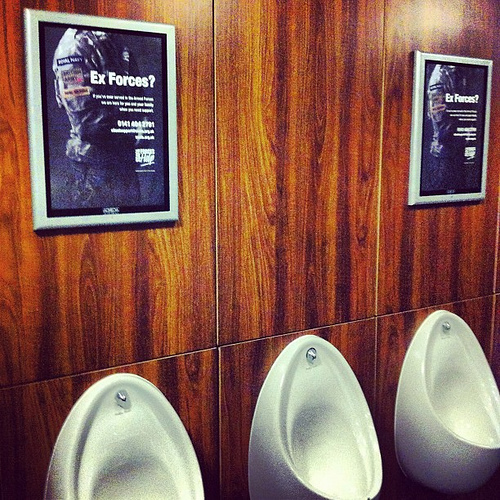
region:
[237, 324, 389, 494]
Urinal in a restroom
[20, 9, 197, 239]
Picture hanging on a bathroom wall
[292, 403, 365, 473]
Bowl portion on a urinal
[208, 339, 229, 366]
Seam between panels on a wall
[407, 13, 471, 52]
Light reflecting off a wall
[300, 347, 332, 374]
Metal portion of a urinal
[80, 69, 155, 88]
Letters on a picture on a wall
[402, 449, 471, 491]
Underside of a urinal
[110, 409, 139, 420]
Manufacturer name on a urinal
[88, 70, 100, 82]
white letter on poster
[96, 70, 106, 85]
white letter on poster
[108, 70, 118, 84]
white letter on poster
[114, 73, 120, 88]
white letter on poster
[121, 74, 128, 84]
white letter on poster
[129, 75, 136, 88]
white letter on poster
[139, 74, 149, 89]
white letter on poster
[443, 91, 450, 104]
white letter on poster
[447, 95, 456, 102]
white letter on poster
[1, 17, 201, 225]
grey frame around poster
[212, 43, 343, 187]
brown wall near poster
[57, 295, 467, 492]
white urinals on wall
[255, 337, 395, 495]
urinals are white and round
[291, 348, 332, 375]
metal button on urinal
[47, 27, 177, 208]
white ad on picture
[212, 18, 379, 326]
brown and wooden panels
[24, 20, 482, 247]
two posters on wall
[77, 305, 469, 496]
urinals near each other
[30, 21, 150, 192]
person in poster picture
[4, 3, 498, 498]
wood panels on wall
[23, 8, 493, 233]
two pictures on wall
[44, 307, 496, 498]
three white urinals on wall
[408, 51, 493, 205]
silver frame on picture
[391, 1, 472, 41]
light reflection on wall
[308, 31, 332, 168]
wood grain on panel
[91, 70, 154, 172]
white words on picture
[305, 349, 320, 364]
shiny metal on urinal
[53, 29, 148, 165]
man's body on picture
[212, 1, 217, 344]
line between two panels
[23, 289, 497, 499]
three white ceramic urinals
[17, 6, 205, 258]
advertisement above a urinal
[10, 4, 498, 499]
two ads above three urinals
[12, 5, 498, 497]
two ads above three urinals on a wooden wall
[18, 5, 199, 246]
a framed advertisement targeted at ex-military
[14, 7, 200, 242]
a framed ad targeted at veterans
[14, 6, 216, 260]
an ad targeted at ex-military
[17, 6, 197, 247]
an ad on the wall targeted at veterans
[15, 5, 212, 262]
bathroom wall advertisement in a frame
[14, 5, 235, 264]
bathroom advertisement targeting ex-military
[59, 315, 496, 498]
Oval urinals.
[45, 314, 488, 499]
White ceramic urinals.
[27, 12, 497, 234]
Silver framed pictures hanging on the wall.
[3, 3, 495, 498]
A brown paneled wall.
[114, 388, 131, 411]
A silver flusher.